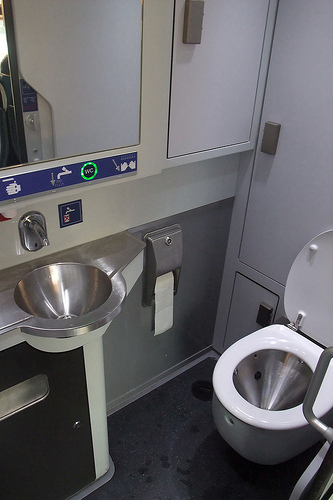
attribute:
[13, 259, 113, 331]
sink — silver 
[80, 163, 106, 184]
button — black 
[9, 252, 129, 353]
sink — silver , bowl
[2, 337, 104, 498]
trashcan — black, silver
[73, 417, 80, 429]
lock — silver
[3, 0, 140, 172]
mirror — reflecting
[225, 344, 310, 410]
top — open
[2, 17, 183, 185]
wall — white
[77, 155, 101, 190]
light — green 